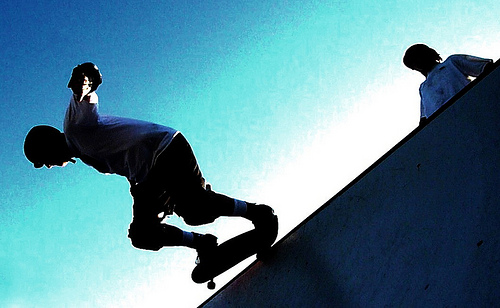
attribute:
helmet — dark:
[15, 111, 65, 173]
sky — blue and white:
[3, 0, 406, 121]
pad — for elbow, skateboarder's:
[45, 57, 116, 98]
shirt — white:
[410, 53, 471, 118]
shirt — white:
[414, 49, 481, 115]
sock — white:
[233, 195, 248, 217]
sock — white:
[179, 228, 194, 245]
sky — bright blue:
[13, 3, 488, 40]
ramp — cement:
[238, 139, 496, 307]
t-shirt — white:
[62, 109, 169, 172]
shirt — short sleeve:
[63, 100, 177, 192]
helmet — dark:
[22, 117, 72, 172]